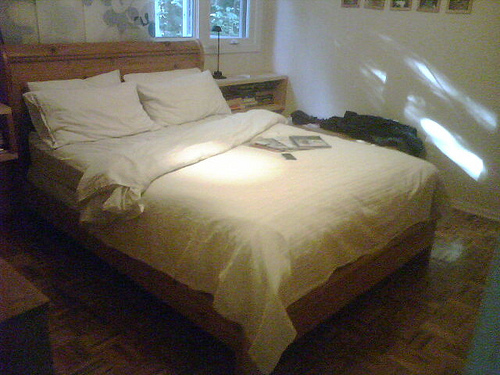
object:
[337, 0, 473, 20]
art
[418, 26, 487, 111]
wall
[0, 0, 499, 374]
bedroom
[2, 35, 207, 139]
headboard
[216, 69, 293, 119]
night stand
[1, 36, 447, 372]
bed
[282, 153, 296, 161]
remote control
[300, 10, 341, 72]
white wall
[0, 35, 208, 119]
brown head/bed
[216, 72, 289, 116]
bookshelf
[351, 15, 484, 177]
sunlight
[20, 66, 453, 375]
cover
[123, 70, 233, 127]
pillows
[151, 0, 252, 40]
window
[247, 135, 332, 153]
books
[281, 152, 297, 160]
phone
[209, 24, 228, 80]
lamp